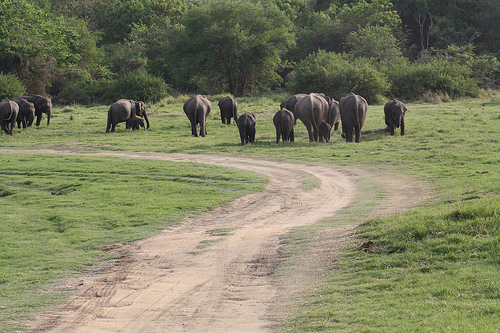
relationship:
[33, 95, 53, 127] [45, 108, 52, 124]
elephant has trunk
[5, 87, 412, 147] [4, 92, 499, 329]
elephants in field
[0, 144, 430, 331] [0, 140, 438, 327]
path in sandy